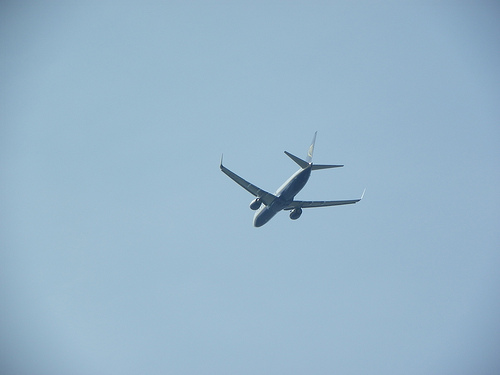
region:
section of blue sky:
[47, 32, 130, 105]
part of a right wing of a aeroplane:
[313, 202, 327, 207]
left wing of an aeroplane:
[235, 177, 250, 191]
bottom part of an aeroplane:
[288, 181, 298, 196]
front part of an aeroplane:
[255, 222, 262, 226]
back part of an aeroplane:
[306, 164, 312, 173]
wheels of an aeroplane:
[276, 203, 283, 213]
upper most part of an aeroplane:
[312, 136, 315, 148]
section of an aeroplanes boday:
[283, 170, 304, 195]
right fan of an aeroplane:
[289, 210, 299, 219]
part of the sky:
[365, 15, 412, 44]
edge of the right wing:
[351, 180, 373, 213]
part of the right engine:
[292, 210, 300, 231]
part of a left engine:
[246, 195, 261, 207]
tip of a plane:
[250, 219, 263, 236]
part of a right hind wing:
[322, 163, 342, 181]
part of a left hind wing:
[290, 137, 307, 176]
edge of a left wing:
[213, 145, 237, 180]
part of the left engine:
[252, 198, 264, 217]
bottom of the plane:
[270, 185, 285, 227]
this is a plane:
[200, 140, 371, 237]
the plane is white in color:
[193, 153, 378, 230]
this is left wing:
[208, 161, 264, 203]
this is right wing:
[302, 187, 368, 224]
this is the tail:
[276, 145, 351, 176]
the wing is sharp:
[215, 153, 257, 190]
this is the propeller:
[247, 193, 262, 212]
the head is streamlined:
[245, 218, 274, 225]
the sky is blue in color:
[1, 0, 498, 121]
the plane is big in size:
[214, 140, 372, 237]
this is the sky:
[6, 56, 173, 347]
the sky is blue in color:
[8, 22, 127, 132]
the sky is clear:
[11, 17, 208, 366]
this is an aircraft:
[215, 129, 370, 235]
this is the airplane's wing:
[289, 191, 364, 210]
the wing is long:
[289, 197, 366, 208]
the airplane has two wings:
[217, 159, 364, 210]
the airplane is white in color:
[278, 192, 289, 207]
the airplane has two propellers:
[248, 196, 301, 218]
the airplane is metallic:
[269, 195, 286, 209]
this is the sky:
[90, 44, 205, 107]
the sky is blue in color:
[101, 205, 174, 290]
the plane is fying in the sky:
[198, 136, 360, 247]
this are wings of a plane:
[305, 192, 365, 225]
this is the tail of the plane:
[286, 129, 340, 186]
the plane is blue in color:
[216, 148, 365, 233]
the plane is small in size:
[205, 136, 395, 235]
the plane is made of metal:
[213, 122, 364, 242]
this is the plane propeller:
[247, 195, 264, 214]